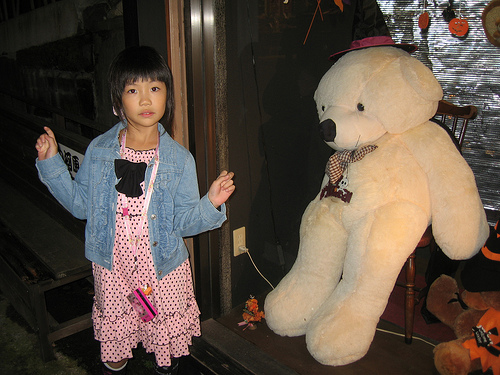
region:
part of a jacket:
[166, 243, 171, 258]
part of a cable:
[256, 225, 263, 282]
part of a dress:
[181, 322, 200, 338]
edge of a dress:
[176, 339, 195, 359]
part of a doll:
[353, 340, 358, 350]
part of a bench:
[56, 257, 81, 302]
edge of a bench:
[225, 334, 229, 341]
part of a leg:
[358, 330, 361, 347]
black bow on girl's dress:
[112, 158, 149, 198]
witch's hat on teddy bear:
[327, 0, 422, 52]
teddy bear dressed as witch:
[423, 219, 498, 372]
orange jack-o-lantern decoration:
[445, 16, 470, 37]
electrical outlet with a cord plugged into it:
[230, 224, 250, 257]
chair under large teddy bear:
[369, 98, 479, 347]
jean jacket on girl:
[36, 119, 226, 279]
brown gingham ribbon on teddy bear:
[322, 142, 379, 186]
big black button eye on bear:
[357, 99, 366, 114]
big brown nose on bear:
[316, 117, 338, 143]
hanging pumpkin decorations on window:
[417, 8, 467, 37]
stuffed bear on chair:
[261, 2, 488, 364]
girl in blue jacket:
[36, 45, 231, 368]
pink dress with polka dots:
[95, 149, 198, 365]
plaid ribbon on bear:
[324, 141, 376, 184]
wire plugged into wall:
[232, 226, 275, 292]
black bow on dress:
[111, 157, 151, 199]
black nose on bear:
[318, 116, 339, 143]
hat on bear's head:
[331, 2, 414, 61]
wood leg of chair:
[403, 252, 419, 339]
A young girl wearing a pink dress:
[96, 47, 213, 369]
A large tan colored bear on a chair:
[261, 54, 475, 344]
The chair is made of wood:
[398, 211, 446, 332]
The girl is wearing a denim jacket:
[87, 54, 208, 272]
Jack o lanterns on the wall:
[406, 0, 476, 47]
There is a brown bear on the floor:
[431, 272, 498, 372]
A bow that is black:
[100, 147, 153, 202]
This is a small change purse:
[118, 281, 157, 343]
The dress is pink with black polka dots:
[93, 197, 203, 355]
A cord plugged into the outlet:
[226, 217, 278, 272]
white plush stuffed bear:
[265, 50, 487, 365]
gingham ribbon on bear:
[323, 145, 376, 180]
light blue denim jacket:
[34, 120, 226, 275]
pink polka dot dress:
[91, 131, 201, 368]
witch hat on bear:
[331, 0, 417, 59]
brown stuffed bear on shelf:
[422, 224, 498, 372]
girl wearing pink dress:
[35, 46, 235, 371]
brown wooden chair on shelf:
[401, 100, 471, 342]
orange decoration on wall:
[448, 17, 467, 37]